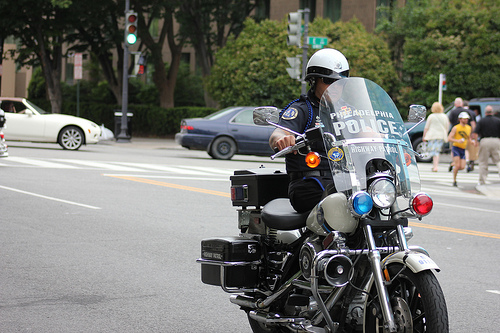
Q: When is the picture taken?
A: Daytime.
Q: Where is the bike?
A: On the road.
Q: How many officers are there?
A: One.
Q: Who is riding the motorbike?
A: The officer.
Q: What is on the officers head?
A: A helmet.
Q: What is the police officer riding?
A: A motorbike.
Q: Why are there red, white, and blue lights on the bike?
A: It's a police bike.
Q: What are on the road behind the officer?
A: Cars.